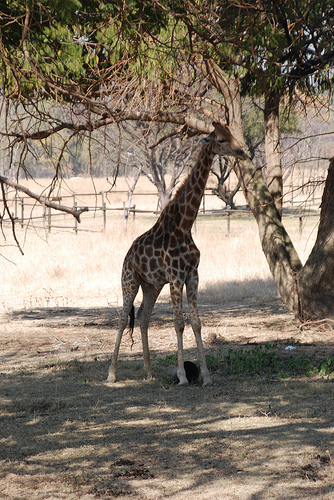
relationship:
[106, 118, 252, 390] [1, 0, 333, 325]
giraffe looking at tree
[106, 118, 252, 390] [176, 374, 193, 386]
giraffe has hoof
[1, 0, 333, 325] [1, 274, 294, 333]
tree has shadow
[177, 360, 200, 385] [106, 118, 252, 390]
dish under giraffe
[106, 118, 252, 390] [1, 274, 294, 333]
giraffe in shadow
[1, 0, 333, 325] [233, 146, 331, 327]
tree has a trunk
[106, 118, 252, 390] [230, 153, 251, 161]
giraffe has a mouth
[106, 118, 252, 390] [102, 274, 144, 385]
giraffe has a leg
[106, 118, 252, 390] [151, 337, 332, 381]
giraffe in grass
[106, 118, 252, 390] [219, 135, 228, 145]
giraffe has an eye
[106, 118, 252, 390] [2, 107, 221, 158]
giraffe by a branch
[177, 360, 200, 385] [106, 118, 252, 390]
dish by giraffe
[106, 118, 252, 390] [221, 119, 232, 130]
giraffe has a horn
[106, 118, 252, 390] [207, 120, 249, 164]
giraffe has a head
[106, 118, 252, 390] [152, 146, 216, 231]
giraffe has a neck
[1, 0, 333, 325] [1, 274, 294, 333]
tree casts a shadow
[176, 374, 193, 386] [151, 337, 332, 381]
hoof in grass